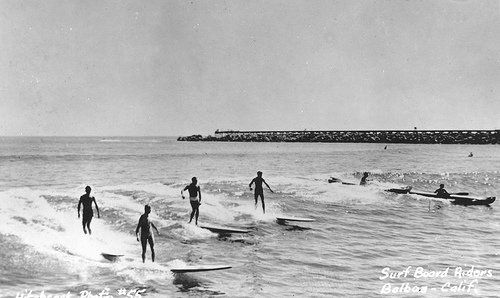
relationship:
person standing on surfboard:
[77, 185, 100, 235] [277, 214, 314, 223]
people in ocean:
[72, 183, 164, 265] [2, 124, 496, 296]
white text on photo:
[363, 265, 497, 296] [9, 12, 497, 295]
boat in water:
[340, 175, 497, 202] [128, 132, 225, 167]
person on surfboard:
[135, 202, 161, 262] [163, 263, 233, 271]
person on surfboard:
[77, 185, 100, 235] [156, 234, 238, 272]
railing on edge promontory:
[210, 127, 498, 134] [175, 125, 497, 140]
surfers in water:
[78, 170, 275, 264] [8, 132, 497, 274]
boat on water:
[327, 176, 496, 206] [1, 137, 498, 296]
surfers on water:
[78, 172, 273, 262] [1, 137, 498, 296]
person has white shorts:
[179, 175, 202, 225] [187, 194, 202, 203]